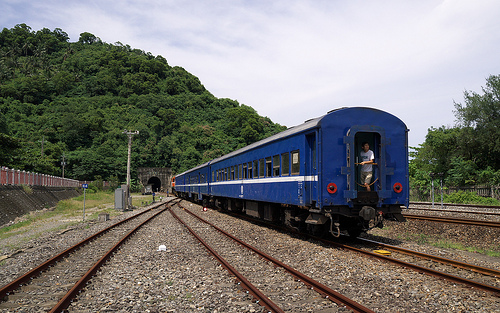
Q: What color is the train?
A: Blue.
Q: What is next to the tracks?
A: Gravel.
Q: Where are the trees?
A: Behind the train.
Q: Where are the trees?
A: On the hillside.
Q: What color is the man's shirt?
A: White.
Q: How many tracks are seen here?
A: Six.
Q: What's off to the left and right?
A: Fencing.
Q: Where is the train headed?
A: Into a tunnel.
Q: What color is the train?
A: Blue.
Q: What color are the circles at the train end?
A: Red.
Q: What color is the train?
A: Blue.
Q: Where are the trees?
A: Surrounding the tunnel.